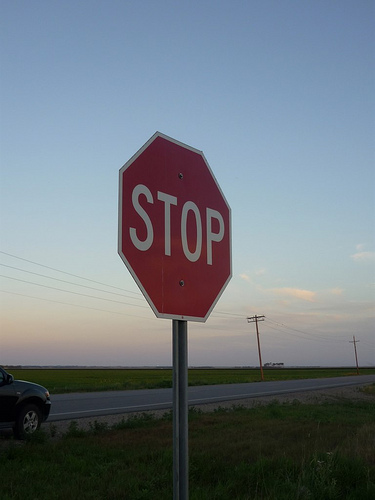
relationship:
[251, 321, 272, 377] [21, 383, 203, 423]
poles beside road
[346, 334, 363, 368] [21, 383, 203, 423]
pole beside road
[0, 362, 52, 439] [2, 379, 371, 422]
car parked beside roadway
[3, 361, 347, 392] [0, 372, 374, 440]
field near road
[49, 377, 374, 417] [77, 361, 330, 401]
line on roadway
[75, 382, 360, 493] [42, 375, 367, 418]
dirt perpendicular to road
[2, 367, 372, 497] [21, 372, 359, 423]
grass growing on side of road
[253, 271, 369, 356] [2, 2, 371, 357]
clouds in sky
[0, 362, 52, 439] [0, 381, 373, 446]
car parked on shoulder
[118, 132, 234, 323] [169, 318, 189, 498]
sign on pole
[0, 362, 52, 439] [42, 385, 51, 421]
car has front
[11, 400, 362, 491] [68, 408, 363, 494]
grass on ground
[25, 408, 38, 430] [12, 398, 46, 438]
rim on tire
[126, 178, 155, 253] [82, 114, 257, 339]
letter written on sign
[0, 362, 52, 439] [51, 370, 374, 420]
car driving on road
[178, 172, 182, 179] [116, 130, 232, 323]
screw on sign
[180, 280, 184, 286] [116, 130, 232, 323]
bolt on sign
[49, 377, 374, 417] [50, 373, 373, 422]
line on side of road